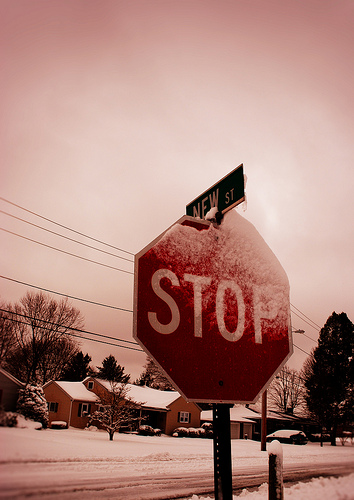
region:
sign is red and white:
[131, 213, 294, 401]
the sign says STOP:
[145, 269, 280, 342]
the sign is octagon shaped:
[115, 216, 293, 403]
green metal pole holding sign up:
[210, 403, 233, 499]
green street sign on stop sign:
[184, 164, 245, 217]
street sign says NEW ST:
[189, 184, 237, 218]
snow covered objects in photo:
[0, 209, 351, 499]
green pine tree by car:
[304, 309, 353, 446]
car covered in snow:
[266, 430, 312, 446]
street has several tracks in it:
[1, 448, 350, 498]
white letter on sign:
[189, 200, 198, 217]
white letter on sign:
[200, 196, 209, 215]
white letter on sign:
[206, 187, 218, 209]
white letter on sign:
[225, 191, 231, 205]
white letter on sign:
[228, 187, 235, 202]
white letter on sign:
[151, 265, 179, 334]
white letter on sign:
[182, 271, 211, 341]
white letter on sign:
[215, 277, 248, 341]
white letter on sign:
[249, 283, 276, 348]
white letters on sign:
[146, 266, 279, 345]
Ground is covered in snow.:
[48, 435, 83, 455]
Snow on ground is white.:
[29, 426, 95, 459]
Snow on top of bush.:
[51, 416, 66, 426]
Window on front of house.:
[176, 405, 194, 423]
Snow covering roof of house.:
[105, 370, 174, 403]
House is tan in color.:
[60, 374, 198, 428]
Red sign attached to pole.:
[193, 378, 239, 435]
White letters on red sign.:
[123, 246, 284, 373]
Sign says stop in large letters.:
[141, 265, 306, 354]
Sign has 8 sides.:
[128, 267, 304, 406]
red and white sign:
[162, 184, 285, 423]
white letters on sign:
[142, 223, 284, 412]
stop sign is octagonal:
[142, 224, 280, 397]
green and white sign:
[171, 148, 236, 227]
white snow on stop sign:
[172, 227, 324, 376]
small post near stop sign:
[257, 429, 299, 498]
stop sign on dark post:
[101, 224, 258, 498]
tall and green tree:
[295, 313, 351, 455]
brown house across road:
[18, 384, 239, 442]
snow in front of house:
[17, 421, 349, 478]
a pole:
[209, 400, 234, 498]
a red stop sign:
[135, 221, 292, 401]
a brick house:
[45, 374, 198, 428]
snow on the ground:
[10, 428, 156, 456]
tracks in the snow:
[23, 456, 339, 475]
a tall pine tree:
[310, 313, 351, 434]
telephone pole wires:
[9, 199, 346, 397]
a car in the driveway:
[256, 422, 315, 454]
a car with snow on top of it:
[265, 427, 307, 442]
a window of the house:
[179, 412, 191, 422]